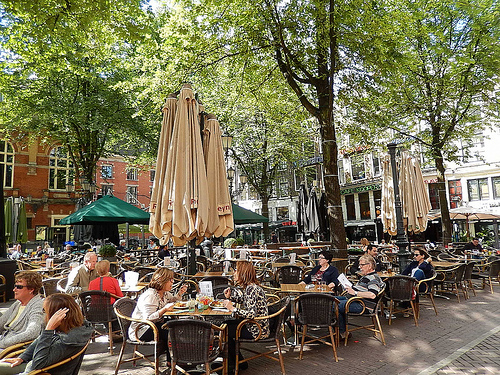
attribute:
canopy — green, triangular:
[44, 181, 166, 237]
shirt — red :
[88, 270, 119, 306]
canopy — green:
[58, 195, 156, 235]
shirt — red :
[88, 275, 122, 303]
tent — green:
[58, 195, 158, 234]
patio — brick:
[307, 272, 496, 374]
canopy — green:
[54, 190, 151, 225]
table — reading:
[158, 289, 272, 354]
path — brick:
[440, 327, 482, 352]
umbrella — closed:
[137, 75, 246, 268]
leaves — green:
[83, 52, 159, 127]